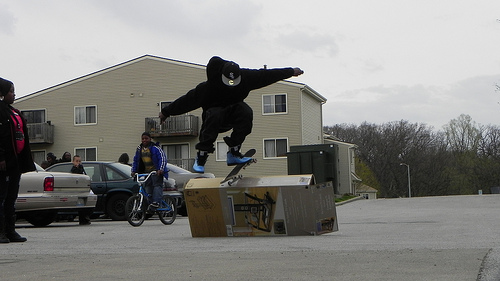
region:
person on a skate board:
[156, 47, 310, 178]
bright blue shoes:
[192, 148, 257, 174]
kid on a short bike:
[125, 129, 182, 227]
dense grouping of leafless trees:
[316, 112, 498, 201]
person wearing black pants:
[0, 73, 38, 247]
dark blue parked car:
[42, 154, 181, 224]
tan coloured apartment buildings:
[8, 48, 383, 203]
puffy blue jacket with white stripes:
[122, 141, 173, 184]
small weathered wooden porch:
[137, 107, 203, 139]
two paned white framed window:
[257, 88, 288, 115]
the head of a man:
[197, 5, 307, 98]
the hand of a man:
[141, 86, 170, 130]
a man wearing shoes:
[179, 133, 273, 197]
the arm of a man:
[147, 63, 218, 142]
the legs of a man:
[164, 86, 292, 171]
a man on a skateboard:
[147, 63, 359, 215]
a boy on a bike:
[110, 112, 187, 244]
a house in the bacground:
[59, 35, 368, 153]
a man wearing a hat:
[193, 40, 258, 92]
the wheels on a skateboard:
[207, 125, 272, 185]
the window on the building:
[260, 94, 285, 114]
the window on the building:
[261, 138, 288, 160]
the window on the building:
[72, 106, 97, 126]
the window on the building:
[73, 147, 95, 159]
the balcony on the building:
[144, 115, 198, 137]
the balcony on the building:
[164, 157, 196, 172]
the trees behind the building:
[321, 113, 498, 200]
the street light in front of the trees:
[400, 161, 410, 200]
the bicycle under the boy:
[127, 169, 176, 225]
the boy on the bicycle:
[125, 132, 177, 227]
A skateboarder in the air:
[152, 49, 307, 189]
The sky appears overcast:
[1, 1, 498, 123]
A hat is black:
[213, 58, 249, 89]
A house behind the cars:
[11, 51, 328, 175]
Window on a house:
[68, 101, 102, 131]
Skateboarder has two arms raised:
[154, 52, 309, 126]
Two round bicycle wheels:
[121, 189, 181, 229]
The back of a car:
[17, 159, 99, 226]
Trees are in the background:
[321, 113, 498, 195]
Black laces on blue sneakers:
[186, 146, 257, 176]